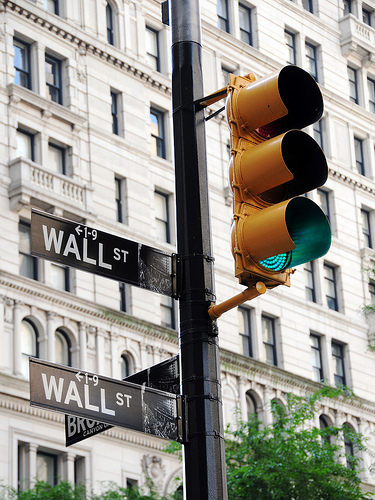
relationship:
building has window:
[1, 0, 373, 497] [14, 30, 31, 90]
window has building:
[14, 30, 31, 90] [1, 0, 373, 497]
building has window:
[1, 0, 373, 497] [46, 47, 63, 107]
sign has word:
[63, 356, 180, 447] [80, 422, 104, 437]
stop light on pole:
[224, 61, 332, 290] [169, 0, 227, 499]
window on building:
[309, 329, 323, 387] [1, 0, 373, 497]